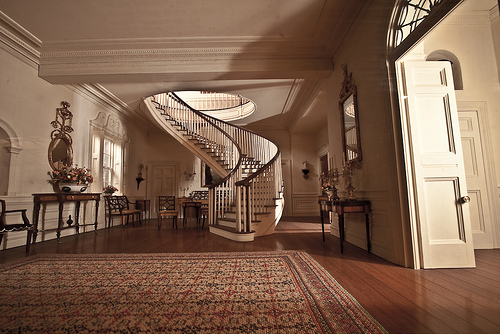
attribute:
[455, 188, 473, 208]
knob — gold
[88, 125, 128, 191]
window — large, on left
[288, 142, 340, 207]
sconce — large, wall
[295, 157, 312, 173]
candle — light-colored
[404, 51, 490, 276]
door — painted , white 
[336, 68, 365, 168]
mirror — rectangle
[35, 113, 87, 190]
mirror — large , ornate  , round  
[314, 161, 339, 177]
candles — cream-colored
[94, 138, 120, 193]
window — large, painted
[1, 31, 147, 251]
wall — white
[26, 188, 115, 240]
table — brown , wooden 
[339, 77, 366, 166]
mirror — rectangle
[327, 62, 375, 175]
mirror — large , ornate metal , rectangular 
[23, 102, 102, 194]
mirror — decorative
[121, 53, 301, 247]
staircase — beautiful, imposing spiral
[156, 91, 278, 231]
staircase — ornate , spiral , opulent 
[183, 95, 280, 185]
bannister — wood 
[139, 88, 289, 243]
stairway — curvy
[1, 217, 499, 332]
floor — shiney, brown, wooden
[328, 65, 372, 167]
mirror — rectangle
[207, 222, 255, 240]
step — white, brown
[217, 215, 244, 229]
step — white, brown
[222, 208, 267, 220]
step — white, brown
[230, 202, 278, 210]
step — white, brown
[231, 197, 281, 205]
step — white, brown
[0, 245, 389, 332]
rug — very large, big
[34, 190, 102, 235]
table — ornate, skinny, dark wood, console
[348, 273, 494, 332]
floor — wooden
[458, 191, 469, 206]
handle — glass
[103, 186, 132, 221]
bench — long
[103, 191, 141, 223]
chairs — fancy, wooden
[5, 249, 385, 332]
persian rug — geometric-patterned, earth-toned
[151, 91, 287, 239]
white staircase — curving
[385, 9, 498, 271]
doorway — open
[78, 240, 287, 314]
rug — colorful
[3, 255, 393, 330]
rug — area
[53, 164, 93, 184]
potted flowers — pink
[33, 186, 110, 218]
table — wooden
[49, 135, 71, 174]
mirror — oval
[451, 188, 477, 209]
door knob — metal , door 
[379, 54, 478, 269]
painted door — white , painted 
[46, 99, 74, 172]
frame — fancy, metal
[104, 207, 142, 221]
upholstery — cream-colored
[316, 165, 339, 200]
candleabra — ornate silver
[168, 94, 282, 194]
trim — dark wook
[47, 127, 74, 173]
mirror — oval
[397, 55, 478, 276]
door — white, large, sturdy, white-painted, wooden